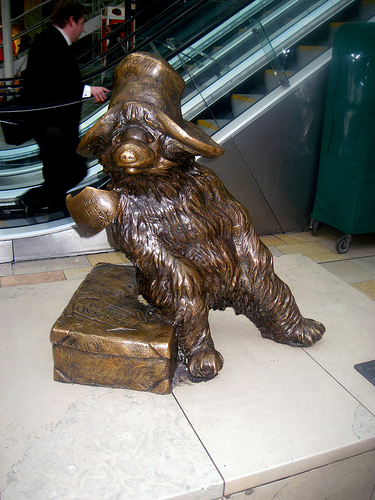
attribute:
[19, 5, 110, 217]
man — light skinned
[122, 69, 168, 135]
statue — brown